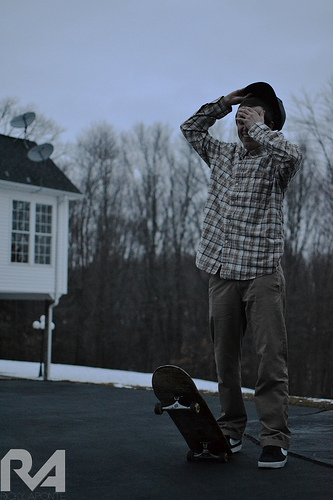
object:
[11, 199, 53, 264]
window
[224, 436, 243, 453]
shoes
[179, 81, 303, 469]
boy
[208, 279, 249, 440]
leg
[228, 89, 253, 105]
hands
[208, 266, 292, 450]
pants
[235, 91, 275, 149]
head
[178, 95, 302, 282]
shirt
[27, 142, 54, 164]
satellite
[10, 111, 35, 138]
satellite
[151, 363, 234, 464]
skateboard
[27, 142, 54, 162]
discs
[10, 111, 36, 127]
discs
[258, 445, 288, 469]
feet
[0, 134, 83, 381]
house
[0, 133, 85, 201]
roof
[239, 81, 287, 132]
cap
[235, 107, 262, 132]
right hand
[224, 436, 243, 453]
foot